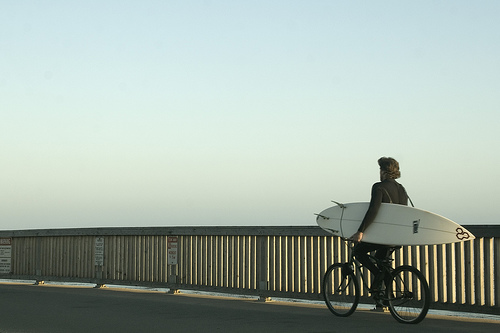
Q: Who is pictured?
A: A man.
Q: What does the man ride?
A: A bicycle.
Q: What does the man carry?
A: A surfboard.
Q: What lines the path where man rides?
A: A wood railing.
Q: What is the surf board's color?
A: White.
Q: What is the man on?
A: Bike.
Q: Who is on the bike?
A: The man.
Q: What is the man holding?
A: Surfboard.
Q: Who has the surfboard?
A: The man.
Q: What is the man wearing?
A: Wetsuit.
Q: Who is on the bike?
A: The man.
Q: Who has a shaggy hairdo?
A: The man.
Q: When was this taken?
A: Daytime.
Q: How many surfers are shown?
A: 1.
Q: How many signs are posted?
A: 3.